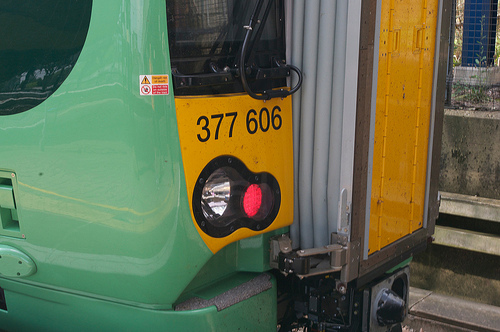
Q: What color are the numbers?
A: Black.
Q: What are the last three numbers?
A: 606.